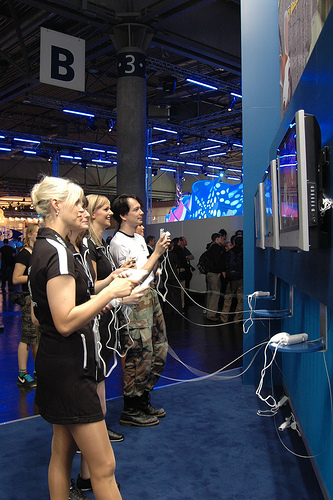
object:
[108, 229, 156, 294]
shirt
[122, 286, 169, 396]
pants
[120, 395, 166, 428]
boots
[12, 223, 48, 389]
woman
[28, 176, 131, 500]
woman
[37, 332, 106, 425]
skirt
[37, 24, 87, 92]
sign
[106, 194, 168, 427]
man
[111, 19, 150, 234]
pole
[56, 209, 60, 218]
earring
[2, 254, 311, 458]
floor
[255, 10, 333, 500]
wall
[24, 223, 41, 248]
head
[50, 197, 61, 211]
ear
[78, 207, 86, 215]
nose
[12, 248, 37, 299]
shirt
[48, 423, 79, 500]
leg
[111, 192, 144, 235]
head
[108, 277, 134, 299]
hand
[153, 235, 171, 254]
hand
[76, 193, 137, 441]
person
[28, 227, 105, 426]
dress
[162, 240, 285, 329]
cable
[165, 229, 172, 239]
joystick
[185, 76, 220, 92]
light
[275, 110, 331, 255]
screen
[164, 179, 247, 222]
sign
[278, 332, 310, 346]
controller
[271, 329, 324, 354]
shelf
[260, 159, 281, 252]
television